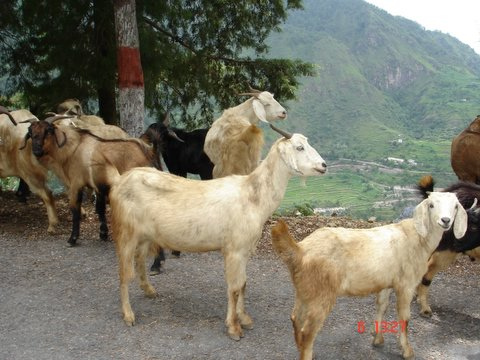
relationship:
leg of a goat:
[108, 227, 150, 327] [90, 116, 330, 309]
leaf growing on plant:
[203, 6, 229, 33] [53, 3, 284, 100]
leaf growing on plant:
[184, 56, 231, 82] [138, 9, 283, 121]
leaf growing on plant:
[273, 62, 299, 79] [137, 12, 276, 100]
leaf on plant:
[243, 54, 265, 81] [1, 3, 314, 204]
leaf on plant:
[138, 75, 162, 92] [1, 2, 303, 179]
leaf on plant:
[38, 30, 64, 60] [12, 0, 314, 224]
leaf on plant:
[155, 97, 176, 133] [1, 3, 314, 204]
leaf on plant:
[52, 43, 84, 62] [12, 0, 314, 224]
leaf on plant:
[152, 36, 178, 63] [12, 0, 314, 224]